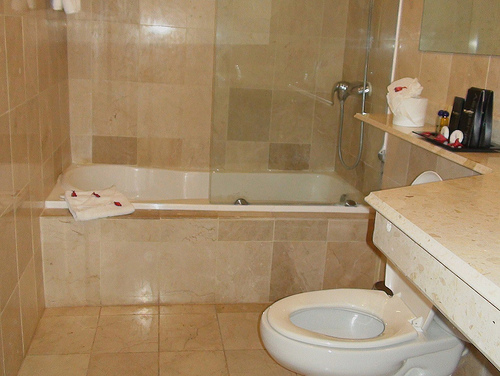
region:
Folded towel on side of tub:
[57, 167, 142, 241]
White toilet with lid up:
[252, 159, 429, 374]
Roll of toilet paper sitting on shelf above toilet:
[376, 70, 432, 135]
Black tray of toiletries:
[408, 75, 498, 144]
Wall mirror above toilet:
[399, 9, 499, 59]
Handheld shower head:
[319, 25, 368, 178]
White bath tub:
[37, 140, 379, 214]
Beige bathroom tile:
[15, 35, 244, 360]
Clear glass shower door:
[200, 6, 387, 218]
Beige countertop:
[336, 150, 496, 307]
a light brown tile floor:
[29, 305, 269, 373]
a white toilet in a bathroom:
[261, 164, 451, 373]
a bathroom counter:
[361, 105, 496, 344]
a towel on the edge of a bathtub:
[66, 171, 146, 233]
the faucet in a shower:
[330, 73, 370, 107]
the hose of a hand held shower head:
[316, 2, 376, 175]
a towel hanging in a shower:
[48, 1, 92, 22]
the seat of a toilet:
[266, 274, 420, 364]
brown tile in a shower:
[90, 12, 200, 164]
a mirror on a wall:
[410, 1, 498, 55]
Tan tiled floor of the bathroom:
[17, 300, 300, 374]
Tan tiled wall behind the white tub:
[72, 1, 342, 171]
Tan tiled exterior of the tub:
[41, 211, 384, 303]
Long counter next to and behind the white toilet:
[352, 110, 499, 371]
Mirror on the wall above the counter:
[416, 0, 497, 56]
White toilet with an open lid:
[257, 171, 469, 373]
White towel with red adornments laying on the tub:
[62, 186, 139, 220]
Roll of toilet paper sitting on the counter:
[392, 94, 431, 126]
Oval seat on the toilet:
[266, 288, 418, 350]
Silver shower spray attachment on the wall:
[329, 3, 379, 171]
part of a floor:
[113, 330, 126, 339]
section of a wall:
[90, 67, 99, 74]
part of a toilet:
[390, 315, 407, 339]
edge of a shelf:
[426, 131, 436, 135]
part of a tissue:
[409, 100, 414, 107]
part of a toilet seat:
[391, 292, 398, 304]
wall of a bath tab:
[183, 244, 208, 258]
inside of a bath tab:
[163, 182, 185, 192]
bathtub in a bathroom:
[45, 143, 388, 241]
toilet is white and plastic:
[236, 170, 486, 375]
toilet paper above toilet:
[385, 71, 444, 137]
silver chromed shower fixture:
[310, 18, 400, 178]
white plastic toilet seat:
[256, 274, 429, 361]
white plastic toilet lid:
[362, 168, 472, 319]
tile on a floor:
[137, 302, 224, 361]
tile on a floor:
[74, 293, 172, 365]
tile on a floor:
[204, 297, 287, 361]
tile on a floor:
[8, 344, 96, 374]